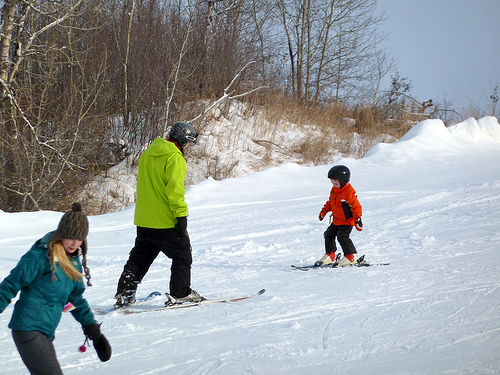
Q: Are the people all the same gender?
A: No, they are both male and female.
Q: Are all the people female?
A: No, they are both male and female.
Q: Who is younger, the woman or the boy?
A: The boy is younger than the woman.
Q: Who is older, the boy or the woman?
A: The woman is older than the boy.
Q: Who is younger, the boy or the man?
A: The boy is younger than the man.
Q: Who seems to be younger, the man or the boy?
A: The boy is younger than the man.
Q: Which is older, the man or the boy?
A: The man is older than the boy.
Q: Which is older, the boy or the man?
A: The man is older than the boy.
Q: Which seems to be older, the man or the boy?
A: The man is older than the boy.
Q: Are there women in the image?
A: Yes, there is a woman.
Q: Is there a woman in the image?
A: Yes, there is a woman.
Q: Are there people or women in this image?
A: Yes, there is a woman.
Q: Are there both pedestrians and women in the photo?
A: No, there is a woman but no pedestrians.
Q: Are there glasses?
A: No, there are no glasses.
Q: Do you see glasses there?
A: No, there are no glasses.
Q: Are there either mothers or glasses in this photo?
A: No, there are no glasses or mothers.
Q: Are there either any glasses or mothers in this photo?
A: No, there are no glasses or mothers.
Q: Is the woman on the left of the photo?
A: Yes, the woman is on the left of the image.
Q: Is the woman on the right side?
A: No, the woman is on the left of the image.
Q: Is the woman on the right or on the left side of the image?
A: The woman is on the left of the image.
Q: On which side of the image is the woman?
A: The woman is on the left of the image.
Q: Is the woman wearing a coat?
A: Yes, the woman is wearing a coat.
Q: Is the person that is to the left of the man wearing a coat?
A: Yes, the woman is wearing a coat.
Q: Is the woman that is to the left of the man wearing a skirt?
A: No, the woman is wearing a coat.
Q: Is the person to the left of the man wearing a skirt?
A: No, the woman is wearing a coat.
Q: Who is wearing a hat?
A: The woman is wearing a hat.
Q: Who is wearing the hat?
A: The woman is wearing a hat.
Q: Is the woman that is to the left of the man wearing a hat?
A: Yes, the woman is wearing a hat.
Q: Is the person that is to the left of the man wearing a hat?
A: Yes, the woman is wearing a hat.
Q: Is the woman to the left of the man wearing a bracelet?
A: No, the woman is wearing a hat.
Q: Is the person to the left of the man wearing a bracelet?
A: No, the woman is wearing a hat.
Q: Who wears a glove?
A: The woman wears a glove.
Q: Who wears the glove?
A: The woman wears a glove.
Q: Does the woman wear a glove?
A: Yes, the woman wears a glove.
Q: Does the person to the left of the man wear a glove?
A: Yes, the woman wears a glove.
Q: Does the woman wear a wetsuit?
A: No, the woman wears a glove.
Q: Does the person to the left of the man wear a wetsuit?
A: No, the woman wears a glove.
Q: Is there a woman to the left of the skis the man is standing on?
A: Yes, there is a woman to the left of the skis.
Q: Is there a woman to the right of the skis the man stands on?
A: No, the woman is to the left of the skis.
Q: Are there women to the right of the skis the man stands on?
A: No, the woman is to the left of the skis.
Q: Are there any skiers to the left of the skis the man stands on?
A: No, there is a woman to the left of the skis.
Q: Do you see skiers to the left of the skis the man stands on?
A: No, there is a woman to the left of the skis.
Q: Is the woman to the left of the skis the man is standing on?
A: Yes, the woman is to the left of the skis.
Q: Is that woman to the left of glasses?
A: No, the woman is to the left of the skis.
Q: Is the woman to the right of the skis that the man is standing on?
A: No, the woman is to the left of the skis.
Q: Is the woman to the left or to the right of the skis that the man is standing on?
A: The woman is to the left of the skis.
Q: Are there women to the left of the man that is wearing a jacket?
A: Yes, there is a woman to the left of the man.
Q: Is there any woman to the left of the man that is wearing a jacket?
A: Yes, there is a woman to the left of the man.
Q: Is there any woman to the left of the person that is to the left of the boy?
A: Yes, there is a woman to the left of the man.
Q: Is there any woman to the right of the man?
A: No, the woman is to the left of the man.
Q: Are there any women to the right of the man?
A: No, the woman is to the left of the man.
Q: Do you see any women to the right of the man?
A: No, the woman is to the left of the man.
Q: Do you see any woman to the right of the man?
A: No, the woman is to the left of the man.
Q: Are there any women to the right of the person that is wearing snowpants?
A: No, the woman is to the left of the man.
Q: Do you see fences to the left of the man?
A: No, there is a woman to the left of the man.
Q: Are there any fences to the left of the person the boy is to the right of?
A: No, there is a woman to the left of the man.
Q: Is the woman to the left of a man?
A: Yes, the woman is to the left of a man.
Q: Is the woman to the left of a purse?
A: No, the woman is to the left of a man.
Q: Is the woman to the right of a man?
A: No, the woman is to the left of a man.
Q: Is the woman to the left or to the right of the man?
A: The woman is to the left of the man.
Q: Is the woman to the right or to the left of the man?
A: The woman is to the left of the man.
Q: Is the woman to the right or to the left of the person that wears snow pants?
A: The woman is to the left of the man.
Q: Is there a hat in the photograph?
A: Yes, there is a hat.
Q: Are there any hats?
A: Yes, there is a hat.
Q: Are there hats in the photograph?
A: Yes, there is a hat.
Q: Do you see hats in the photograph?
A: Yes, there is a hat.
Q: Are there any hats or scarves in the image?
A: Yes, there is a hat.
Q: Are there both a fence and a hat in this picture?
A: No, there is a hat but no fences.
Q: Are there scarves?
A: No, there are no scarves.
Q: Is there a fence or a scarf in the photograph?
A: No, there are no scarves or fences.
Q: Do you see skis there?
A: Yes, there are skis.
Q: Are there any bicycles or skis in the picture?
A: Yes, there are skis.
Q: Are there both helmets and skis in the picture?
A: Yes, there are both skis and a helmet.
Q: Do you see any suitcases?
A: No, there are no suitcases.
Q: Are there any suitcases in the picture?
A: No, there are no suitcases.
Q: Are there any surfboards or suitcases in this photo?
A: No, there are no suitcases or surfboards.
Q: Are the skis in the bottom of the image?
A: Yes, the skis are in the bottom of the image.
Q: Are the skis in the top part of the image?
A: No, the skis are in the bottom of the image.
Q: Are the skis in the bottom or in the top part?
A: The skis are in the bottom of the image.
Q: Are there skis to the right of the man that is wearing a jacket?
A: Yes, there are skis to the right of the man.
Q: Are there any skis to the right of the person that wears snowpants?
A: Yes, there are skis to the right of the man.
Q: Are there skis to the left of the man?
A: No, the skis are to the right of the man.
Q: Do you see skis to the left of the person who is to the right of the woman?
A: No, the skis are to the right of the man.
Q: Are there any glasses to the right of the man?
A: No, there are skis to the right of the man.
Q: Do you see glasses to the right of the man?
A: No, there are skis to the right of the man.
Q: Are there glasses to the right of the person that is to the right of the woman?
A: No, there are skis to the right of the man.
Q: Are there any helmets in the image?
A: Yes, there is a helmet.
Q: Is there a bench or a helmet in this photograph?
A: Yes, there is a helmet.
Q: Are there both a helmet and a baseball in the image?
A: No, there is a helmet but no baseballs.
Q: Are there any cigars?
A: No, there are no cigars.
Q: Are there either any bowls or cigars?
A: No, there are no cigars or bowls.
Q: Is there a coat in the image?
A: Yes, there is a coat.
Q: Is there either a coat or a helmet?
A: Yes, there is a coat.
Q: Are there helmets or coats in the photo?
A: Yes, there is a coat.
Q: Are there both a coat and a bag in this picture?
A: No, there is a coat but no bags.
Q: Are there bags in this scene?
A: No, there are no bags.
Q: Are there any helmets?
A: Yes, there is a helmet.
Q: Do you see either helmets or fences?
A: Yes, there is a helmet.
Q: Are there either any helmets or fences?
A: Yes, there is a helmet.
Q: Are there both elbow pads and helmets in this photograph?
A: No, there is a helmet but no elbow pads.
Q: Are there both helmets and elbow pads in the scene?
A: No, there is a helmet but no elbow pads.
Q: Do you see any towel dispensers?
A: No, there are no towel dispensers.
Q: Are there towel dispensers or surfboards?
A: No, there are no towel dispensers or surfboards.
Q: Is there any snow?
A: Yes, there is snow.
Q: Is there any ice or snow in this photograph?
A: Yes, there is snow.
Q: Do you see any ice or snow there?
A: Yes, there is snow.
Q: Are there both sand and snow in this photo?
A: No, there is snow but no sand.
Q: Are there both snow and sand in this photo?
A: No, there is snow but no sand.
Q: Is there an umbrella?
A: No, there are no umbrellas.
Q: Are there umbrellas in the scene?
A: No, there are no umbrellas.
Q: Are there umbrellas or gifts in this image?
A: No, there are no umbrellas or gifts.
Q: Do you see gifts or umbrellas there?
A: No, there are no umbrellas or gifts.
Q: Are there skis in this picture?
A: Yes, there are skis.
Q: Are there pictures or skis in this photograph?
A: Yes, there are skis.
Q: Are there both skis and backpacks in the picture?
A: No, there are skis but no backpacks.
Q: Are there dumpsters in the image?
A: No, there are no dumpsters.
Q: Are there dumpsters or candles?
A: No, there are no dumpsters or candles.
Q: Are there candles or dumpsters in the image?
A: No, there are no dumpsters or candles.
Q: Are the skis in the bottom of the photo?
A: Yes, the skis are in the bottom of the image.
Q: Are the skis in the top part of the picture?
A: No, the skis are in the bottom of the image.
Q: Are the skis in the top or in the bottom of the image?
A: The skis are in the bottom of the image.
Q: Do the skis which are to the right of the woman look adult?
A: Yes, the skis are adult.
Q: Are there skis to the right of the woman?
A: Yes, there are skis to the right of the woman.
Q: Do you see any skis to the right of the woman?
A: Yes, there are skis to the right of the woman.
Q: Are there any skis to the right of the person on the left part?
A: Yes, there are skis to the right of the woman.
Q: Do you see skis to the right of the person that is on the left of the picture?
A: Yes, there are skis to the right of the woman.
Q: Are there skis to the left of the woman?
A: No, the skis are to the right of the woman.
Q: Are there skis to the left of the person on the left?
A: No, the skis are to the right of the woman.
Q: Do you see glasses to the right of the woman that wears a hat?
A: No, there are skis to the right of the woman.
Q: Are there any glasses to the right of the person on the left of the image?
A: No, there are skis to the right of the woman.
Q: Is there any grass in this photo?
A: Yes, there is grass.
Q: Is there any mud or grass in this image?
A: Yes, there is grass.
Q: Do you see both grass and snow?
A: Yes, there are both grass and snow.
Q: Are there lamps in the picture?
A: No, there are no lamps.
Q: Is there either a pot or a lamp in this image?
A: No, there are no lamps or pots.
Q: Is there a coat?
A: Yes, there is a coat.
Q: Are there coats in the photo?
A: Yes, there is a coat.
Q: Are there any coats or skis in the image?
A: Yes, there is a coat.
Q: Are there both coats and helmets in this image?
A: Yes, there are both a coat and a helmet.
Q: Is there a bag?
A: No, there are no bags.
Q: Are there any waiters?
A: No, there are no waiters.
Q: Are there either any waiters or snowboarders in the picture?
A: No, there are no waiters or snowboarders.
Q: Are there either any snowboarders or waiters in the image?
A: No, there are no waiters or snowboarders.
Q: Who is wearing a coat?
A: The boy is wearing a coat.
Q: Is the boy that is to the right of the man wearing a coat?
A: Yes, the boy is wearing a coat.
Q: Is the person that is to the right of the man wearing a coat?
A: Yes, the boy is wearing a coat.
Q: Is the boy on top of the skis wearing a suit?
A: No, the boy is wearing a coat.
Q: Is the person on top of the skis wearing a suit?
A: No, the boy is wearing a coat.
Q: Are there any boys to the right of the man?
A: Yes, there is a boy to the right of the man.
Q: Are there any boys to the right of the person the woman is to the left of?
A: Yes, there is a boy to the right of the man.